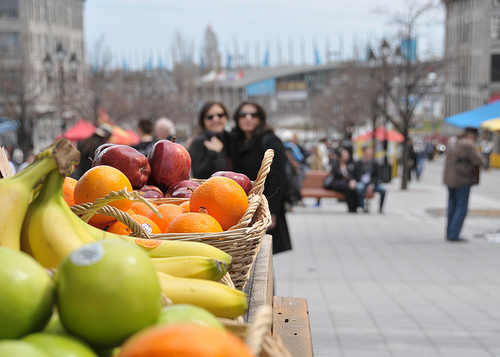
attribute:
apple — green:
[1, 246, 55, 339]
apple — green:
[54, 239, 159, 347]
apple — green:
[105, 303, 229, 356]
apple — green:
[20, 332, 100, 356]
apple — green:
[1, 338, 45, 355]